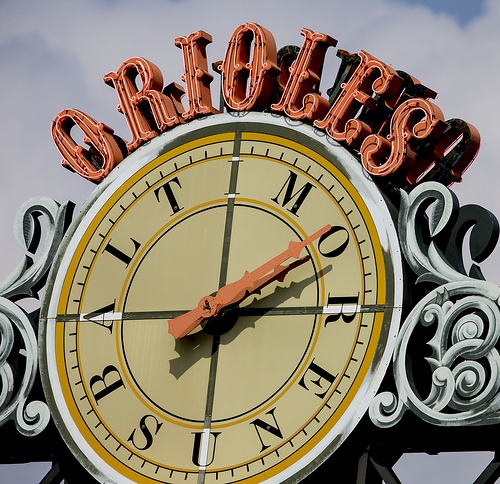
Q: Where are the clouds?
A: In the sky.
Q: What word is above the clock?
A: Orioles.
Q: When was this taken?
A: Daytime.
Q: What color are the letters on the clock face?
A: Black.